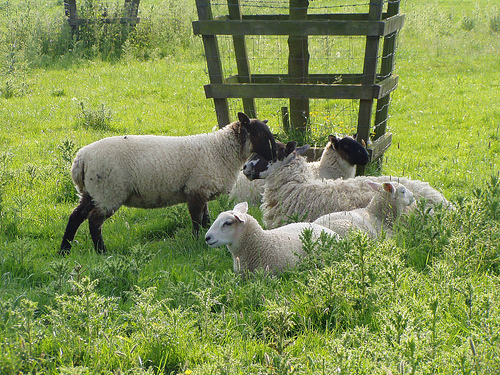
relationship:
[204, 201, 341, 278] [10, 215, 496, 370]
closest sheep in grass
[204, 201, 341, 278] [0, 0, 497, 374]
closest sheep in grass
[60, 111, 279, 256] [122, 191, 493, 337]
sheep in grass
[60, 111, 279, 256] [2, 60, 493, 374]
sheep in grass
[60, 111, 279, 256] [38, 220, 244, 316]
sheep in grass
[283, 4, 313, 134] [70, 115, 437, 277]
trunk behind through sheep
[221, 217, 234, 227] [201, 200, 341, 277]
eye of closest sheep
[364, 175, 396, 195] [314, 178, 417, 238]
ears of sheep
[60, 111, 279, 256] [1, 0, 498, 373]
sheep on farm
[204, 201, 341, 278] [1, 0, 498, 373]
closest sheep on farm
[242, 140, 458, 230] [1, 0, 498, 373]
sheep on farm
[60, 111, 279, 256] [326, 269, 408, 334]
sheep eating grass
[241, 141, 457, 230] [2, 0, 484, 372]
sheep in sunshine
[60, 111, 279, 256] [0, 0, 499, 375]
sheep in grass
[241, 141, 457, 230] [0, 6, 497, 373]
sheep in field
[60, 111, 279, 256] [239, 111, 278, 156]
sheep has face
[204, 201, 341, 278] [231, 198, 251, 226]
closest sheep has ears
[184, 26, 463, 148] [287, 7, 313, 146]
wooden boards around trunk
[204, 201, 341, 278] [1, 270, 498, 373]
closest sheep resting in pasture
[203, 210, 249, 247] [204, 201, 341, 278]
head of closest sheep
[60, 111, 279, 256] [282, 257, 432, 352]
sheep lying in grass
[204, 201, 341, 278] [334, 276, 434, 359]
closest sheep lying in grass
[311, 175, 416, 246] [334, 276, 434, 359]
sheep lying in grass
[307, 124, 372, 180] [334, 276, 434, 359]
sheep lying in grass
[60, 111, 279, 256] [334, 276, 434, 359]
sheep lying in grass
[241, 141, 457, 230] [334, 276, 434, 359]
sheep lying in grass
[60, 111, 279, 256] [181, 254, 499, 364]
sheep relaxing in grass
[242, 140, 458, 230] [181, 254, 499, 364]
sheep relaxing in grass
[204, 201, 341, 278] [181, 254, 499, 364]
closest sheep relaxing in grass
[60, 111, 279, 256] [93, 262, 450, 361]
sheep standing in grass